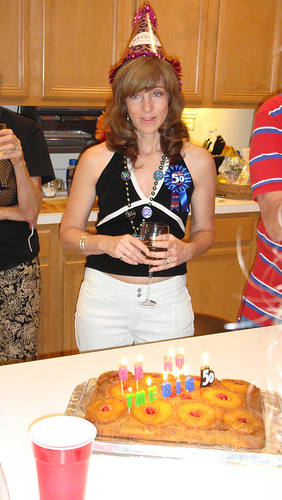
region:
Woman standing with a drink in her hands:
[60, 56, 214, 333]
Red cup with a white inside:
[25, 416, 97, 499]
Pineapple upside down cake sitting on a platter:
[84, 370, 265, 448]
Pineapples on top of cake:
[89, 381, 257, 431]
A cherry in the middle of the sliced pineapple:
[188, 409, 200, 417]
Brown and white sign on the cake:
[195, 364, 215, 385]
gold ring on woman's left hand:
[163, 255, 169, 265]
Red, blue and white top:
[234, 87, 278, 330]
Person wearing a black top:
[0, 105, 53, 266]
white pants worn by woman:
[73, 268, 194, 351]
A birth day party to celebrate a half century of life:
[2, 2, 281, 498]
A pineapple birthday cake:
[66, 369, 278, 457]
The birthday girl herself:
[57, 0, 210, 349]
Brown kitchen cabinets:
[1, 0, 278, 107]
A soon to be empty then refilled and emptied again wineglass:
[130, 217, 172, 313]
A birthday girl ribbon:
[163, 165, 196, 212]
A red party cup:
[19, 409, 98, 497]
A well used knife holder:
[198, 118, 228, 189]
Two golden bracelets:
[75, 233, 99, 266]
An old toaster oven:
[22, 108, 126, 151]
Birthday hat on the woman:
[103, 2, 190, 88]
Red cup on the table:
[23, 410, 100, 498]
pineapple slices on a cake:
[179, 397, 278, 446]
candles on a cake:
[113, 355, 230, 415]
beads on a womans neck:
[97, 114, 190, 257]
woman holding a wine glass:
[132, 205, 184, 294]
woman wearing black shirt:
[82, 143, 210, 296]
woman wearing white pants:
[47, 254, 215, 359]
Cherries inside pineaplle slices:
[179, 396, 255, 428]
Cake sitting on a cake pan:
[74, 376, 281, 467]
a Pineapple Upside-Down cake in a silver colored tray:
[67, 370, 280, 464]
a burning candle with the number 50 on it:
[197, 350, 215, 387]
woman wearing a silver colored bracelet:
[77, 231, 89, 259]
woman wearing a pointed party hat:
[103, 0, 190, 157]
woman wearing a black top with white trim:
[85, 131, 193, 277]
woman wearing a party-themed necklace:
[121, 133, 172, 237]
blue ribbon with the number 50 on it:
[162, 164, 190, 213]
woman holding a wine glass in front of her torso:
[118, 218, 186, 306]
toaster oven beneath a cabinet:
[18, 1, 116, 153]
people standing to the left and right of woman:
[0, 2, 281, 364]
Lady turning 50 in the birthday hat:
[57, 1, 220, 346]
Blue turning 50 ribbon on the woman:
[161, 162, 192, 216]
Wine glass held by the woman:
[131, 219, 171, 312]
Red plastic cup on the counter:
[25, 413, 99, 498]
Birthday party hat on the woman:
[104, 1, 186, 89]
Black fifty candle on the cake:
[198, 347, 217, 390]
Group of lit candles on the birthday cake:
[116, 345, 219, 414]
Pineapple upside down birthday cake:
[86, 368, 267, 450]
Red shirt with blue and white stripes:
[235, 94, 280, 333]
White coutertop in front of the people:
[1, 321, 281, 498]